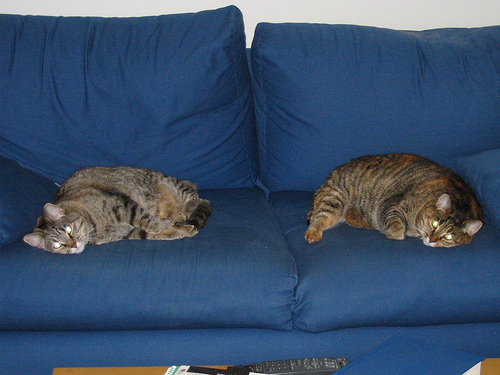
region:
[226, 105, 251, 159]
edge of a cushion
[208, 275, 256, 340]
part of a chair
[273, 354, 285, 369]
part of a remote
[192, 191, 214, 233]
part of a tail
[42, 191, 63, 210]
edge of an ear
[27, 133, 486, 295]
Cats lying on the sofa.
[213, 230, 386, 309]
The sofa is blue.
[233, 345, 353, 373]
Remote on the table.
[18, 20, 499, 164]
Pillow cushions on the sofa.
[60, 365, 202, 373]
The table is brown.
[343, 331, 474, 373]
The book is blue.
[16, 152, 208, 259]
The cat is a grey tiger.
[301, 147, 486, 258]
The cat is a grey and brown tiger.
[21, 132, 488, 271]
Cats looking at the camera.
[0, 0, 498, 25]
The wall is white.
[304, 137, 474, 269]
this is a cat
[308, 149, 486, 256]
the cat is lying on a sofa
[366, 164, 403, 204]
the cat is fat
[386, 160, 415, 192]
the cat is brown in color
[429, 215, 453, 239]
the eyes are open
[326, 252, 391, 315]
this is the cusion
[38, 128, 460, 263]
the cats are two in number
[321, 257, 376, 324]
the cusion is blus=e in color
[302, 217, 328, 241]
this is the leg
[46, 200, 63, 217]
this is the ear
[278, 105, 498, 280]
the cat is laying down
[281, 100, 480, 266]
the cat is striped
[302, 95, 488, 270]
this cat is brown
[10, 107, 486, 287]
the cats are together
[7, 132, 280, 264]
this cat is grey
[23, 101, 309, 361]
the cat is striped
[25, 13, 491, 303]
they are on a couch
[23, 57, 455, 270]
the couch is blue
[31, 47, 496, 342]
there are two cats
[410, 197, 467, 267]
the eyes are glowing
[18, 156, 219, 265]
fat black and grey kitten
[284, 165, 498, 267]
fat black and grey kitten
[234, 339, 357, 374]
grey remote with butins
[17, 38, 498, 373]
Cats sitting on a blue couch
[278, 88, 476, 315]
Cat lounging on blue couch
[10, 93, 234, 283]
Cat lounging on blue couch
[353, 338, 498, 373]
Blue book with white pages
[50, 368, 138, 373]
Light brown wood grain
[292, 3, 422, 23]
White wall paint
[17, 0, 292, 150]
Blue sofa cushion